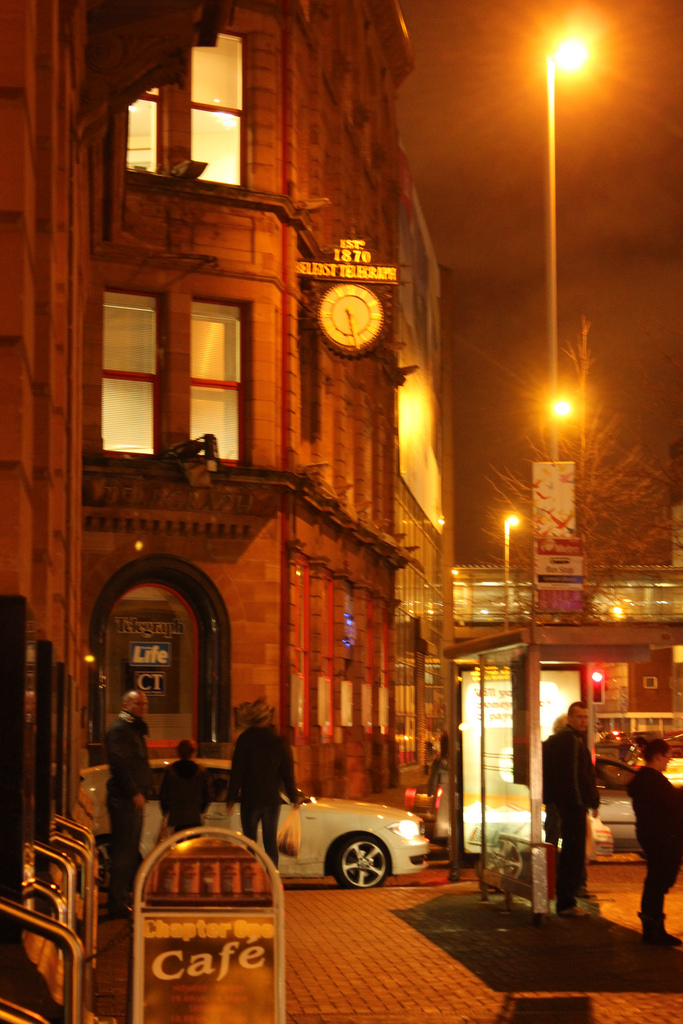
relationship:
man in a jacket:
[228, 699, 294, 881] [228, 728, 294, 793]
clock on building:
[321, 283, 390, 354] [70, 83, 440, 876]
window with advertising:
[112, 565, 223, 752] [105, 611, 189, 684]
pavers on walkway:
[83, 886, 680, 1022] [299, 907, 409, 1021]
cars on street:
[75, 757, 428, 891] [6, 717, 681, 891]